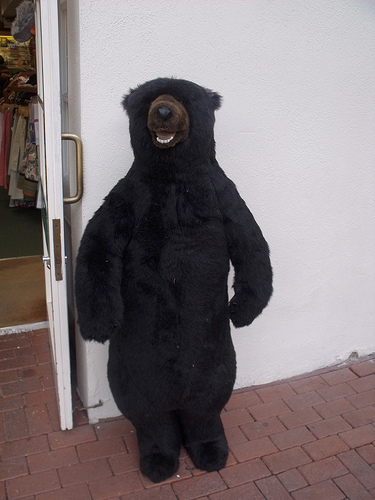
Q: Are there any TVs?
A: No, there are no tvs.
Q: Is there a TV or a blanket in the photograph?
A: No, there are no televisions or blankets.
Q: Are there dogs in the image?
A: No, there are no dogs.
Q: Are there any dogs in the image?
A: No, there are no dogs.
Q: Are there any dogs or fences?
A: No, there are no dogs or fences.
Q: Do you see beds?
A: No, there are no beds.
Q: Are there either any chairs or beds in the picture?
A: No, there are no beds or chairs.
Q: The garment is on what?
A: The garment is on the door.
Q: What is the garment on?
A: The garment is on the door.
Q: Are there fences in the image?
A: No, there are no fences.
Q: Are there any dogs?
A: No, there are no dogs.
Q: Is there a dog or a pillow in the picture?
A: No, there are no dogs or pillows.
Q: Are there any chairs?
A: No, there are no chairs.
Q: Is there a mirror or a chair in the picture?
A: No, there are no chairs or mirrors.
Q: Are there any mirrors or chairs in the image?
A: No, there are no chairs or mirrors.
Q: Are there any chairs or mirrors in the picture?
A: No, there are no chairs or mirrors.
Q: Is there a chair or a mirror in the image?
A: No, there are no chairs or mirrors.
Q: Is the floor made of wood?
A: Yes, the floor is made of wood.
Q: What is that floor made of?
A: The floor is made of wood.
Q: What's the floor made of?
A: The floor is made of wood.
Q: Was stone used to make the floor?
A: No, the floor is made of wood.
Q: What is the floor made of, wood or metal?
A: The floor is made of wood.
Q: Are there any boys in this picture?
A: No, there are no boys.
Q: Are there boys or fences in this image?
A: No, there are no boys or fences.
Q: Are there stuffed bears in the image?
A: Yes, there is a stuffed bear.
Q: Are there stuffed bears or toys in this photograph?
A: Yes, there is a stuffed bear.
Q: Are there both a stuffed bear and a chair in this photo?
A: No, there is a stuffed bear but no chairs.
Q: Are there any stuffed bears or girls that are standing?
A: Yes, the stuffed bear is standing.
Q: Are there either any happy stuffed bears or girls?
A: Yes, there is a happy stuffed bear.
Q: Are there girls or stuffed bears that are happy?
A: Yes, the stuffed bear is happy.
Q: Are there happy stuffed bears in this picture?
A: Yes, there is a happy stuffed bear.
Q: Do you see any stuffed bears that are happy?
A: Yes, there is a happy stuffed bear.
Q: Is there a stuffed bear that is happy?
A: Yes, there is a stuffed bear that is happy.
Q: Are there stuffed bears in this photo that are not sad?
A: Yes, there is a happy stuffed bear.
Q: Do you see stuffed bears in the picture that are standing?
A: Yes, there is a stuffed bear that is standing.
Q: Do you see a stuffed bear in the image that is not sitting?
A: Yes, there is a stuffed bear that is standing .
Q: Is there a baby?
A: No, there are no babies.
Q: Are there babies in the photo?
A: No, there are no babies.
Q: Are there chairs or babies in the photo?
A: No, there are no babies or chairs.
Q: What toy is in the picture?
A: The toy is a stuffed bear.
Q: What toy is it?
A: The toy is a stuffed bear.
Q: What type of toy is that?
A: This is a stuffed bear.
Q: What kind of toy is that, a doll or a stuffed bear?
A: This is a stuffed bear.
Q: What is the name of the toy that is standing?
A: The toy is a stuffed bear.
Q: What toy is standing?
A: The toy is a stuffed bear.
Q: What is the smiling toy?
A: The toy is a stuffed bear.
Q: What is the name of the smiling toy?
A: The toy is a stuffed bear.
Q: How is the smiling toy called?
A: The toy is a stuffed bear.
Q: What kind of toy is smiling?
A: The toy is a stuffed bear.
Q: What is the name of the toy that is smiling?
A: The toy is a stuffed bear.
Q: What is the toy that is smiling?
A: The toy is a stuffed bear.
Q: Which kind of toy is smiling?
A: The toy is a stuffed bear.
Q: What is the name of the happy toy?
A: The toy is a stuffed bear.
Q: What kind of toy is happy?
A: The toy is a stuffed bear.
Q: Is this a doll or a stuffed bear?
A: This is a stuffed bear.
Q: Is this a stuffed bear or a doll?
A: This is a stuffed bear.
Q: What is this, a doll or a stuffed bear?
A: This is a stuffed bear.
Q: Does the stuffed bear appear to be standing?
A: Yes, the stuffed bear is standing.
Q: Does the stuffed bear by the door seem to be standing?
A: Yes, the stuffed bear is standing.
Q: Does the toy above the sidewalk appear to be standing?
A: Yes, the stuffed bear is standing.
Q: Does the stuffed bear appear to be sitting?
A: No, the stuffed bear is standing.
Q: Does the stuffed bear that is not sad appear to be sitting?
A: No, the stuffed bear is standing.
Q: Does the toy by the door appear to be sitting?
A: No, the stuffed bear is standing.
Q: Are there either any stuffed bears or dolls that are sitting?
A: No, there is a stuffed bear but it is standing.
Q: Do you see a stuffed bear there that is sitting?
A: No, there is a stuffed bear but it is standing.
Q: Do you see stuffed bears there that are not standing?
A: No, there is a stuffed bear but it is standing.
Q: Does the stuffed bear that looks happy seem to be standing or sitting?
A: The stuffed bear is standing.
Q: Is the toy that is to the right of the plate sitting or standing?
A: The stuffed bear is standing.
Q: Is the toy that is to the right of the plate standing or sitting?
A: The stuffed bear is standing.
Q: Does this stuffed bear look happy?
A: Yes, the stuffed bear is happy.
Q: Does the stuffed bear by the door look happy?
A: Yes, the stuffed bear is happy.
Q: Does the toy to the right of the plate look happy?
A: Yes, the stuffed bear is happy.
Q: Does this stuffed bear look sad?
A: No, the stuffed bear is happy.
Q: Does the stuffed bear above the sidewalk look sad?
A: No, the stuffed bear is happy.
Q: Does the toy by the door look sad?
A: No, the stuffed bear is happy.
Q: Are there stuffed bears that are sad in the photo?
A: No, there is a stuffed bear but it is happy.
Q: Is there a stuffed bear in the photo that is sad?
A: No, there is a stuffed bear but it is happy.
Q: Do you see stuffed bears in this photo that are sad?
A: No, there is a stuffed bear but it is happy.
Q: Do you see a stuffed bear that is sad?
A: No, there is a stuffed bear but it is happy.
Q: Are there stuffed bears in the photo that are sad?
A: No, there is a stuffed bear but it is happy.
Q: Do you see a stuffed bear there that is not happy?
A: No, there is a stuffed bear but it is happy.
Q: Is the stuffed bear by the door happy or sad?
A: The stuffed bear is happy.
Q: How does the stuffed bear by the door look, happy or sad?
A: The stuffed bear is happy.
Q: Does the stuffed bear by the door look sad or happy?
A: The stuffed bear is happy.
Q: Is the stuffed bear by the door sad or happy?
A: The stuffed bear is happy.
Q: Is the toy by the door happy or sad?
A: The stuffed bear is happy.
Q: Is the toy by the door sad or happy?
A: The stuffed bear is happy.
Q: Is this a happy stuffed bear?
A: Yes, this is a happy stuffed bear.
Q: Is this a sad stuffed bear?
A: No, this is a happy stuffed bear.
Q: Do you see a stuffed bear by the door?
A: Yes, there is a stuffed bear by the door.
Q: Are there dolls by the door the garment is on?
A: No, there is a stuffed bear by the door.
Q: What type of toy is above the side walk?
A: The toy is a stuffed bear.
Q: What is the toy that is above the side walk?
A: The toy is a stuffed bear.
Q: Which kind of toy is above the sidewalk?
A: The toy is a stuffed bear.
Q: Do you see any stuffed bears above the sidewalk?
A: Yes, there is a stuffed bear above the sidewalk.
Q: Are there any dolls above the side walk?
A: No, there is a stuffed bear above the side walk.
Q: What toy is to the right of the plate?
A: The toy is a stuffed bear.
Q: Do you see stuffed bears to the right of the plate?
A: Yes, there is a stuffed bear to the right of the plate.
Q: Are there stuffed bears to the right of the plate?
A: Yes, there is a stuffed bear to the right of the plate.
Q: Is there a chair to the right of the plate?
A: No, there is a stuffed bear to the right of the plate.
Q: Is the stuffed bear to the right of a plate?
A: Yes, the stuffed bear is to the right of a plate.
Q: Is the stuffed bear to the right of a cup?
A: No, the stuffed bear is to the right of a plate.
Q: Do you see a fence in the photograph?
A: No, there are no fences.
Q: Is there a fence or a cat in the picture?
A: No, there are no fences or cats.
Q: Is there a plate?
A: Yes, there is a plate.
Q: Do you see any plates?
A: Yes, there is a plate.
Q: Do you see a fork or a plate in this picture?
A: Yes, there is a plate.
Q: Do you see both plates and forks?
A: No, there is a plate but no forks.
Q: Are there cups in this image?
A: No, there are no cups.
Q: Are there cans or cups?
A: No, there are no cups or cans.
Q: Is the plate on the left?
A: Yes, the plate is on the left of the image.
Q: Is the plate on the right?
A: No, the plate is on the left of the image.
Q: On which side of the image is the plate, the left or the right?
A: The plate is on the left of the image.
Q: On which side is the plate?
A: The plate is on the left of the image.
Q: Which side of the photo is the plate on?
A: The plate is on the left of the image.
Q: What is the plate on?
A: The plate is on the door.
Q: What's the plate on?
A: The plate is on the door.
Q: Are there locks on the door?
A: No, there is a plate on the door.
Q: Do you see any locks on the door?
A: No, there is a plate on the door.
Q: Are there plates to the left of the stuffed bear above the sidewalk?
A: Yes, there is a plate to the left of the stuffed bear.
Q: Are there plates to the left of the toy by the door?
A: Yes, there is a plate to the left of the stuffed bear.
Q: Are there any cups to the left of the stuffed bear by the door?
A: No, there is a plate to the left of the stuffed bear.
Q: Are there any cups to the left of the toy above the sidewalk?
A: No, there is a plate to the left of the stuffed bear.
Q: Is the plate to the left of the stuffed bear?
A: Yes, the plate is to the left of the stuffed bear.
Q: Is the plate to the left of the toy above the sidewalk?
A: Yes, the plate is to the left of the stuffed bear.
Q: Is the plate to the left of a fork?
A: No, the plate is to the left of the stuffed bear.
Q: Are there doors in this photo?
A: Yes, there is a door.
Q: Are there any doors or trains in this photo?
A: Yes, there is a door.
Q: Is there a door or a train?
A: Yes, there is a door.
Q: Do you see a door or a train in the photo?
A: Yes, there is a door.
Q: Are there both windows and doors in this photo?
A: No, there is a door but no windows.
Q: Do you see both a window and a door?
A: No, there is a door but no windows.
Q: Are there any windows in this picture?
A: No, there are no windows.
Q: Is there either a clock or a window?
A: No, there are no windows or clocks.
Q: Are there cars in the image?
A: No, there are no cars.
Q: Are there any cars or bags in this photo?
A: No, there are no cars or bags.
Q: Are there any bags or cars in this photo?
A: No, there are no cars or bags.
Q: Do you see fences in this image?
A: No, there are no fences.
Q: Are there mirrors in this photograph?
A: No, there are no mirrors.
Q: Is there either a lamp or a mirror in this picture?
A: No, there are no mirrors or lamps.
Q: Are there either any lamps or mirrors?
A: No, there are no mirrors or lamps.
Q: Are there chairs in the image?
A: No, there are no chairs.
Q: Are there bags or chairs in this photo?
A: No, there are no chairs or bags.